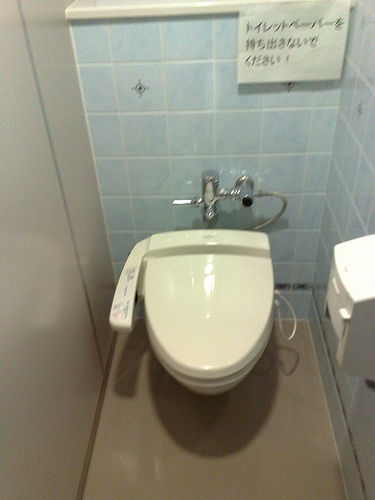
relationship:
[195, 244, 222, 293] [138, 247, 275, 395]
light reflection on seat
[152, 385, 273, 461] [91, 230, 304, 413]
shadow under toilet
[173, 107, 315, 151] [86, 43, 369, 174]
tile on wall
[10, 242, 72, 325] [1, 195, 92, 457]
reflection on wall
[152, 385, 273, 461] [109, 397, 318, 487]
shadow on floor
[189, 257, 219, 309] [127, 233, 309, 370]
light on toilet seat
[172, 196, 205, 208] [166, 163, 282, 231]
flusher handle made of metal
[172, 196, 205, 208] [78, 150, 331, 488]
flusher handle on a toilet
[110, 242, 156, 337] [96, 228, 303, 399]
controls on toilet side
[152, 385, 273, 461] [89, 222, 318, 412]
shadow of toilet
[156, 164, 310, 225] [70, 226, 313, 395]
silverware behind toilet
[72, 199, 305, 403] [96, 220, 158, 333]
toilet with controls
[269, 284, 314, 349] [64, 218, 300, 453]
cord on toilet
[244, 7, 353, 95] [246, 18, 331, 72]
paper with writing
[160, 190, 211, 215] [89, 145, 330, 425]
flusher handle on toilet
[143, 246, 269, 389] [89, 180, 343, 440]
lid of toilet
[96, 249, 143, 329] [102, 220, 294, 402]
armrest of toilet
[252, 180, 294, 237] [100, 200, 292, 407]
pipe above toilet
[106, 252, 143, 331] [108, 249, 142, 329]
markings on armrest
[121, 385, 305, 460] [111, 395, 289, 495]
shadow on floor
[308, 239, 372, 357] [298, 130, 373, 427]
container on wall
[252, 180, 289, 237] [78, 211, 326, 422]
pipe of toilet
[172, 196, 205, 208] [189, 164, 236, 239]
flusher handle mounted on pipe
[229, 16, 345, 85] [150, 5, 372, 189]
writing on wall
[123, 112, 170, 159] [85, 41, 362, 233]
tile on wall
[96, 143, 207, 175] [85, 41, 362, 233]
grout on wall